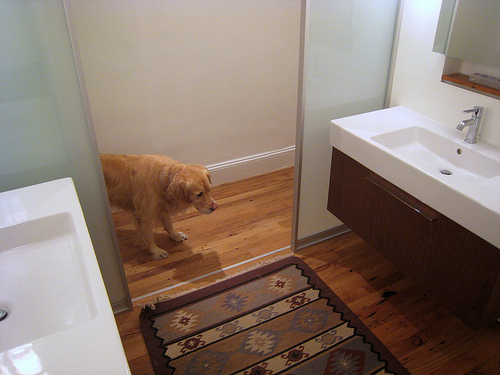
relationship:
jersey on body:
[117, 161, 141, 210] [97, 154, 189, 222]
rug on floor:
[158, 251, 388, 356] [351, 254, 459, 337]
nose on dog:
[199, 199, 236, 221] [105, 118, 291, 259]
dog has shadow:
[105, 118, 291, 259] [165, 250, 225, 280]